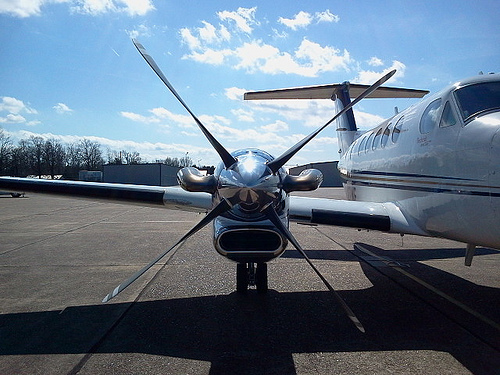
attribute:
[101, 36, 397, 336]
propeller — still, white, black, large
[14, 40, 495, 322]
airplane — large